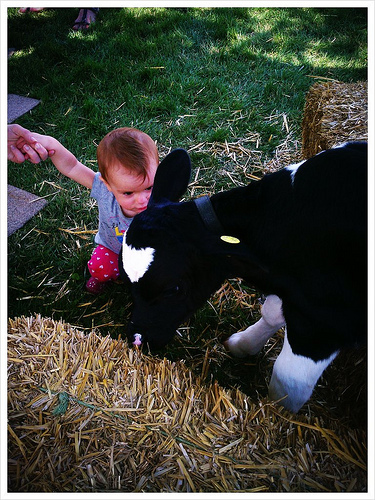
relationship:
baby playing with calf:
[16, 127, 160, 295] [136, 186, 343, 368]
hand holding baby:
[8, 122, 42, 164] [16, 127, 160, 295]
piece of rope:
[86, 400, 94, 412] [24, 372, 236, 470]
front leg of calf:
[268, 298, 346, 414] [119, 135, 368, 417]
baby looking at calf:
[16, 127, 160, 295] [119, 135, 368, 417]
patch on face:
[121, 226, 155, 283] [101, 210, 187, 367]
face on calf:
[101, 210, 187, 367] [120, 143, 374, 396]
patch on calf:
[121, 226, 155, 283] [120, 143, 374, 396]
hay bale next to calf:
[9, 314, 369, 490] [108, 149, 365, 409]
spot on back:
[282, 154, 311, 182] [222, 136, 365, 206]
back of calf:
[222, 136, 365, 206] [119, 135, 368, 417]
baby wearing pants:
[81, 116, 143, 263] [84, 242, 126, 289]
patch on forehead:
[121, 226, 155, 283] [118, 220, 168, 294]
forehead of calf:
[118, 220, 168, 294] [108, 149, 365, 409]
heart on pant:
[99, 246, 104, 250] [86, 242, 121, 284]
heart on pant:
[103, 251, 108, 256] [86, 242, 121, 284]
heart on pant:
[108, 259, 112, 265] [86, 242, 121, 284]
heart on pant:
[99, 263, 103, 268] [86, 242, 121, 284]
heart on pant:
[103, 273, 108, 277] [86, 242, 121, 284]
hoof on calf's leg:
[218, 327, 252, 359] [240, 306, 272, 351]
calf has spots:
[119, 135, 368, 417] [121, 233, 150, 282]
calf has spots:
[119, 135, 368, 417] [330, 143, 346, 148]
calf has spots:
[119, 135, 368, 417] [285, 163, 303, 174]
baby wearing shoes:
[16, 127, 160, 295] [81, 239, 137, 291]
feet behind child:
[11, 3, 103, 35] [46, 126, 179, 297]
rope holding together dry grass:
[38, 386, 281, 481] [7, 311, 368, 493]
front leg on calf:
[255, 325, 344, 413] [119, 135, 368, 417]